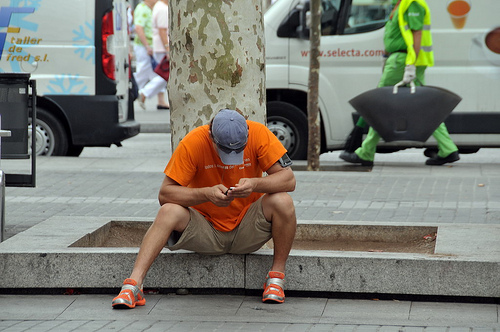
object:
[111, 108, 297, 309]
man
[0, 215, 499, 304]
curb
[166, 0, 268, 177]
tree trunk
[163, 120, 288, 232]
shirt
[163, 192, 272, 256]
shorts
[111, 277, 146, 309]
shoe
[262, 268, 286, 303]
shoe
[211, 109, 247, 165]
cap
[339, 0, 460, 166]
man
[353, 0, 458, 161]
clothing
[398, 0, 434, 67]
vest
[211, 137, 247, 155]
sunglasses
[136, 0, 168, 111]
passerby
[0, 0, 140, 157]
truck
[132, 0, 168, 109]
passerby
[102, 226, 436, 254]
dirt area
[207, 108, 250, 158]
man's head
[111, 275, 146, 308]
man's feet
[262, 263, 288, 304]
man's feet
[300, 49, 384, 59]
www.selecta.com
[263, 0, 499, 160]
van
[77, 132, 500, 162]
road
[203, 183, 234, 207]
hand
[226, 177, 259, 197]
hand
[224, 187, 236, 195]
cell phone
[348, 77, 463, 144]
bag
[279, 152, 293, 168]
ipod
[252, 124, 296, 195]
arm